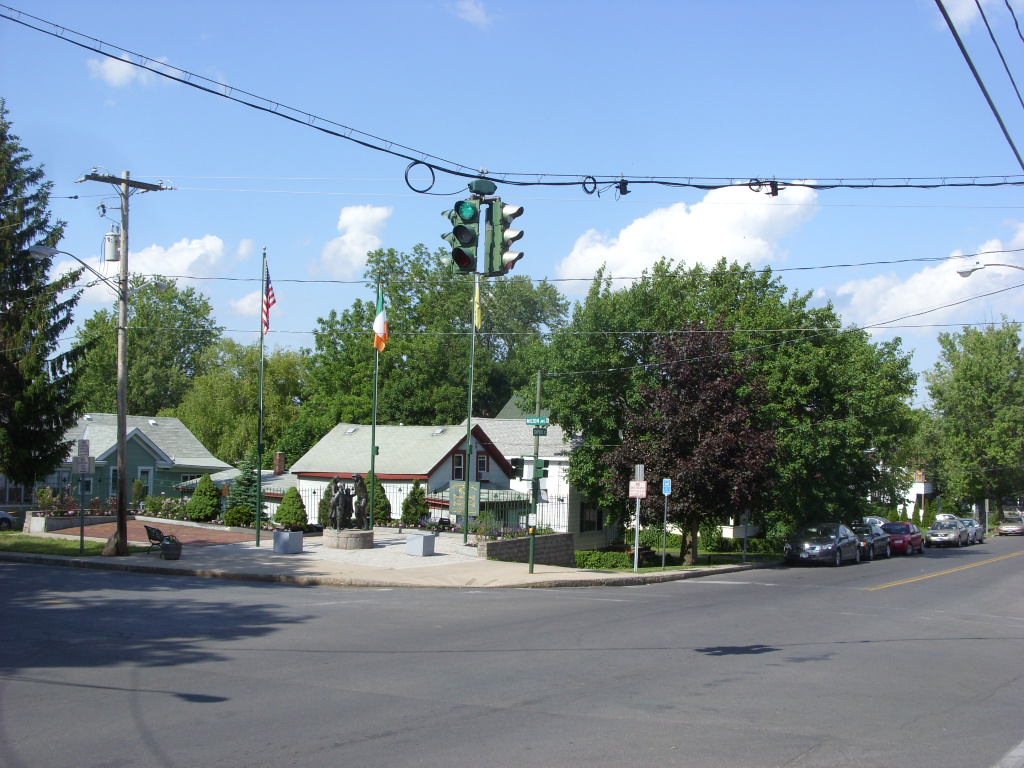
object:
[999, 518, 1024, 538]
car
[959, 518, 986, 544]
car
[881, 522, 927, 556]
car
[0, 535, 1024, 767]
street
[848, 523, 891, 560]
car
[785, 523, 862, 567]
car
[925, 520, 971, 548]
car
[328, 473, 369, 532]
statue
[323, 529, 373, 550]
base